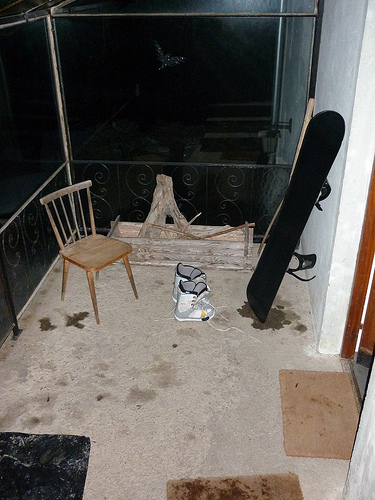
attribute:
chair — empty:
[39, 178, 138, 325]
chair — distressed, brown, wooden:
[44, 184, 145, 315]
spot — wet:
[234, 301, 288, 331]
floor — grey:
[0, 240, 350, 498]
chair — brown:
[55, 186, 139, 281]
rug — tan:
[278, 365, 359, 460]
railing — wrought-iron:
[1, 154, 295, 266]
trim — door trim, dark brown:
[321, 228, 374, 382]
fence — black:
[0, 159, 293, 348]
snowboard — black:
[219, 96, 362, 333]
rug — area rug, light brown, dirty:
[278, 368, 335, 473]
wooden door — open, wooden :
[338, 157, 373, 359]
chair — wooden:
[20, 177, 152, 320]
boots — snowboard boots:
[165, 259, 246, 336]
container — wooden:
[105, 216, 258, 273]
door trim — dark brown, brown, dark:
[334, 232, 363, 360]